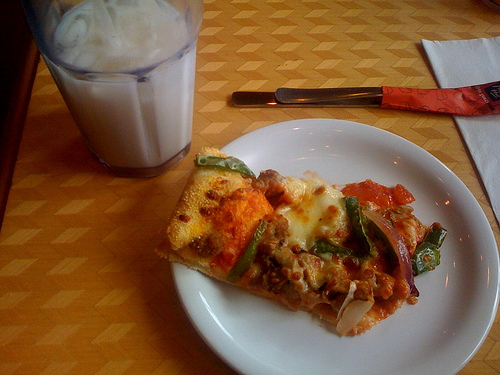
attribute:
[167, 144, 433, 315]
pizza — green, orange, white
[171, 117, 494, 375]
plate — close, round, shiny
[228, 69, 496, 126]
silverware — wrapped, grey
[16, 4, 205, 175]
cup — close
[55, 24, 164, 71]
ice — cubes 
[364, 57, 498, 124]
paper — red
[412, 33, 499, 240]
napkin — white 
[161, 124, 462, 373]
plate — white 